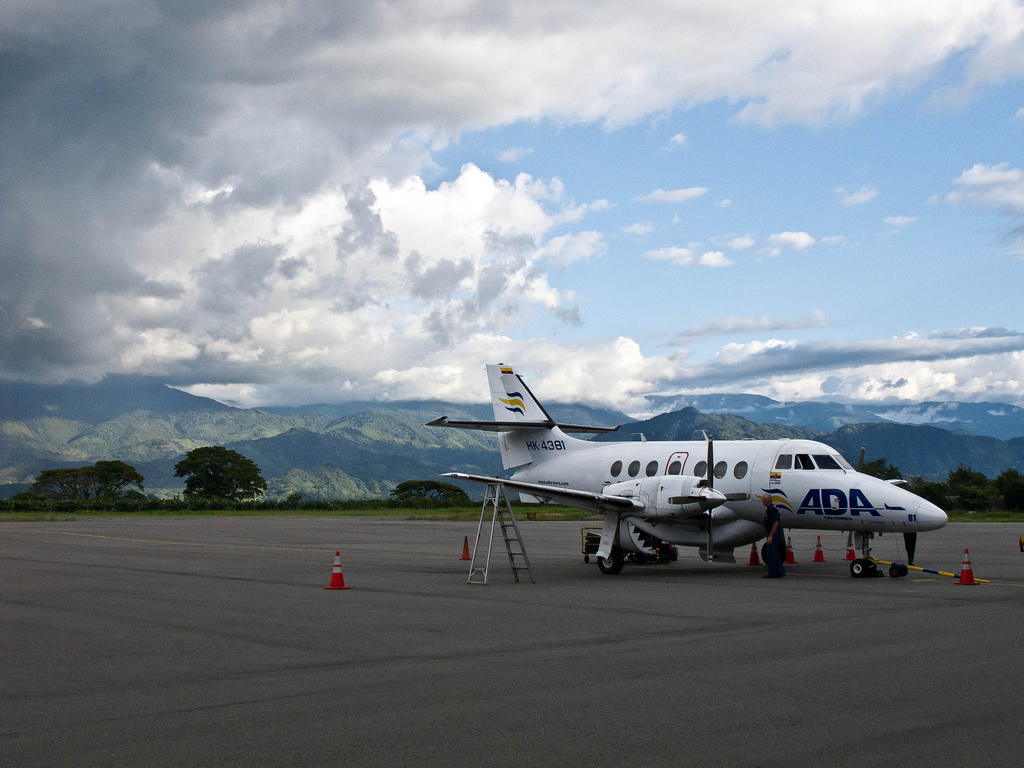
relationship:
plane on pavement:
[446, 342, 961, 585] [7, 515, 1017, 742]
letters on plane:
[781, 474, 892, 529] [355, 318, 978, 597]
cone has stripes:
[325, 551, 352, 590] [325, 538, 989, 582]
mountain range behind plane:
[9, 363, 1021, 504] [407, 329, 943, 571]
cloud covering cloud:
[9, 7, 1021, 453] [0, 0, 1024, 410]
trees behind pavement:
[14, 413, 1021, 532] [9, 510, 1021, 765]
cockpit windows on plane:
[770, 446, 859, 479] [366, 340, 972, 569]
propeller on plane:
[647, 419, 792, 510] [379, 363, 1017, 631]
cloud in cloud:
[0, 0, 1024, 410] [0, 0, 1024, 410]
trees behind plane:
[173, 445, 269, 502] [402, 348, 954, 560]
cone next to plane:
[308, 532, 352, 587] [407, 329, 943, 571]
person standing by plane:
[737, 474, 822, 587] [387, 357, 960, 587]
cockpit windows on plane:
[774, 454, 793, 471] [366, 340, 972, 569]